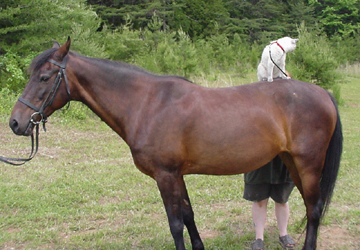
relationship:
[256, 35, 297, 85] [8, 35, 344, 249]
cat on top of horse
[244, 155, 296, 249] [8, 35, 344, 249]
person behind horse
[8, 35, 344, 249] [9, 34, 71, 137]
horse has head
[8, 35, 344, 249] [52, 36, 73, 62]
horse has ear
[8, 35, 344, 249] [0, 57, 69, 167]
horse wearing harness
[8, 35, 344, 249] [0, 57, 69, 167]
horse has harness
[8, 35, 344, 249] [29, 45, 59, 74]
horse has hair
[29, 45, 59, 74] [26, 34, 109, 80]
hair on top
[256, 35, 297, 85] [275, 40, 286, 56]
cat wearing collar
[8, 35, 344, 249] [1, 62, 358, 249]
horse standing in grass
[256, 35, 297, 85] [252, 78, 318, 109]
cat seated on hind quarters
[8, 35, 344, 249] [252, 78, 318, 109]
horse has hind quarters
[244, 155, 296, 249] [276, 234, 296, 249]
person wearing sandals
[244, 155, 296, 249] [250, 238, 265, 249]
person wearing sandals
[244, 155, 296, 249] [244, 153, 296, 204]
person wearing shorts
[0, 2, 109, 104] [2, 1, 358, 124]
tree in background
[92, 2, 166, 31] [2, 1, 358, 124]
tree in background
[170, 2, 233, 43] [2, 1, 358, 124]
tree in background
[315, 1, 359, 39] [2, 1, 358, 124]
tree in background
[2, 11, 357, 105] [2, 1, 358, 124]
vegetation in background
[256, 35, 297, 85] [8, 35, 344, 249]
cat sitting on horse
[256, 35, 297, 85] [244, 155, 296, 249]
cat looking at person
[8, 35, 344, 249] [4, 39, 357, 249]
horse in a field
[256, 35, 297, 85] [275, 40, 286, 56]
cat wearing a collar